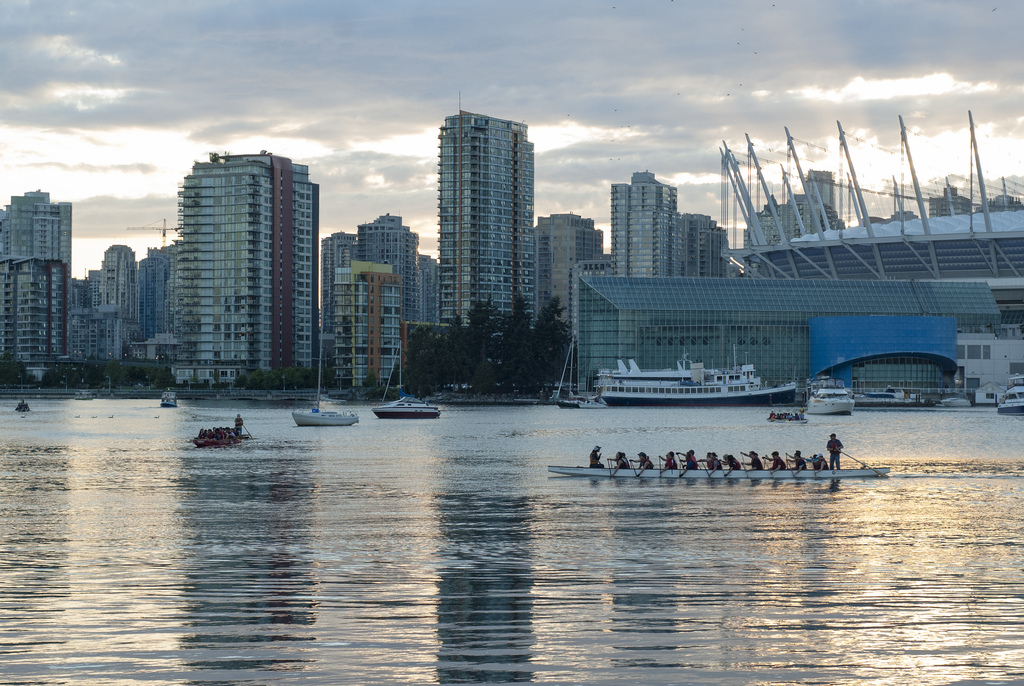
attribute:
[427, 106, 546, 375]
building — tallest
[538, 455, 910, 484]
canoe — large, white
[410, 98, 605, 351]
building — tall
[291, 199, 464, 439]
building — bricked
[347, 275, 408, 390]
windows — white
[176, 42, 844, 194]
sky — gray, cloudy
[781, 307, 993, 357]
wall — blue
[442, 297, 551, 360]
tree — big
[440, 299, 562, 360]
leaves — green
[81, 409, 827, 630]
water — clear, open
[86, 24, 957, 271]
sky — cloudy, morning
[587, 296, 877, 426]
boat — large, long, white, blue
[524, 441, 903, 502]
racing boat — long, thin, white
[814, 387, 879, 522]
man — standing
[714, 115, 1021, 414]
building — stadium looking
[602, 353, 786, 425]
ship — big, cruise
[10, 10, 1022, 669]
picture — outdoors